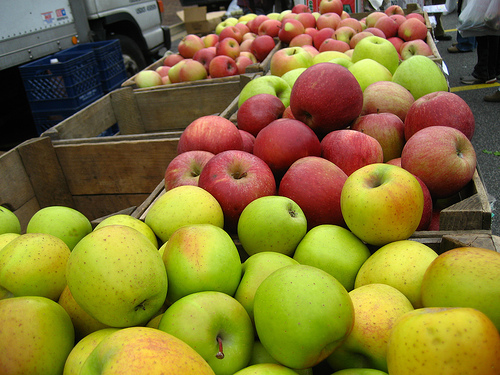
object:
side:
[0, 2, 171, 126]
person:
[456, 0, 498, 86]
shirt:
[457, 0, 498, 26]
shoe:
[459, 74, 499, 84]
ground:
[426, 17, 499, 235]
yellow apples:
[2, 162, 497, 373]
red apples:
[164, 62, 477, 225]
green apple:
[0, 162, 500, 375]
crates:
[0, 133, 184, 219]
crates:
[41, 75, 258, 144]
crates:
[156, 222, 498, 364]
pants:
[470, 29, 499, 82]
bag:
[459, 0, 500, 39]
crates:
[17, 39, 130, 139]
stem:
[215, 332, 225, 359]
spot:
[213, 174, 217, 177]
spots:
[323, 303, 326, 307]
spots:
[190, 314, 193, 317]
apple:
[0, 0, 500, 375]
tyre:
[97, 23, 153, 70]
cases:
[0, 0, 500, 375]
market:
[0, 0, 500, 375]